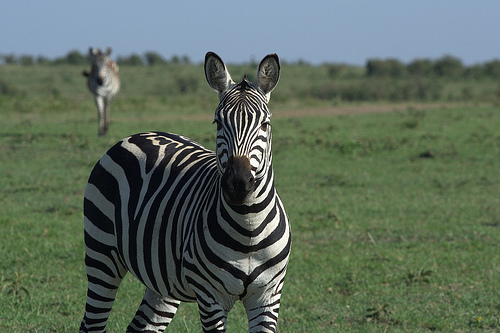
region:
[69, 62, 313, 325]
white and black striped zebra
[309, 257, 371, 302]
long green and yellow grass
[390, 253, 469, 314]
long green and yellow grass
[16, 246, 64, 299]
long green and yellow grass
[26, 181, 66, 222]
long green and yellow grass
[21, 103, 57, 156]
long green and yellow grass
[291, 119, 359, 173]
long green and yellow grass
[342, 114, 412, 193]
long green and yellow grass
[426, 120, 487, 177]
long green and yellow grass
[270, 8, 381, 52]
white clouds in blue sky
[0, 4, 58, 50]
white clouds in blue sky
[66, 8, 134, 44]
white clouds in blue sky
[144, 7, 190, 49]
white clouds in blue sky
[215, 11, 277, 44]
white clouds in blue sky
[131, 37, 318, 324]
black and white striped zebra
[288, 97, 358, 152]
short green and brown grass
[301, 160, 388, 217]
short green and brown grass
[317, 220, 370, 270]
short green and brown grass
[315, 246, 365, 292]
short green and brown grass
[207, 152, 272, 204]
the zebra has a nose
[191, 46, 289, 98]
the zebra has ears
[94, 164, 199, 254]
the zebra has stripes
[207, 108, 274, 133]
the zebra has eyes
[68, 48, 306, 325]
the zebra is standing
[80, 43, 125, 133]
the zebra walking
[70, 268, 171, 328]
the zebra has back legs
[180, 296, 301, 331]
the zebra has front legs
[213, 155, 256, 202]
the nose is black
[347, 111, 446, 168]
the patches are small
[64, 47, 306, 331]
A zebra in the foreground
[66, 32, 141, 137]
A Zebra in the background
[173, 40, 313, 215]
Zebra is looking at the camera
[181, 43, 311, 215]
Front view of the zebra's face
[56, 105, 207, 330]
Side view of the Zebra's body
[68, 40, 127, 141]
Zebra in the background is blurred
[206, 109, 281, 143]
Zebra's eyes are black in color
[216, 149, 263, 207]
Zebra's mouth is black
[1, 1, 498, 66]
The sky is clear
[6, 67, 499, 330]
Zebra's are on a grass landscape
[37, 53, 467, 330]
a zebra that is outside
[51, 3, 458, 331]
a zebra in a field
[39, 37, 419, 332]
a zebra standing outside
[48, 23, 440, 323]
a black and white zebra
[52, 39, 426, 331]
a black and white zebra standing in the grass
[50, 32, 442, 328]
an area with zebras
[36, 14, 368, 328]
a field with zebras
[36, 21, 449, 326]
zebras walking outside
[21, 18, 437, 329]
a field with walking zebras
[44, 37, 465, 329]
an area with walking zebras